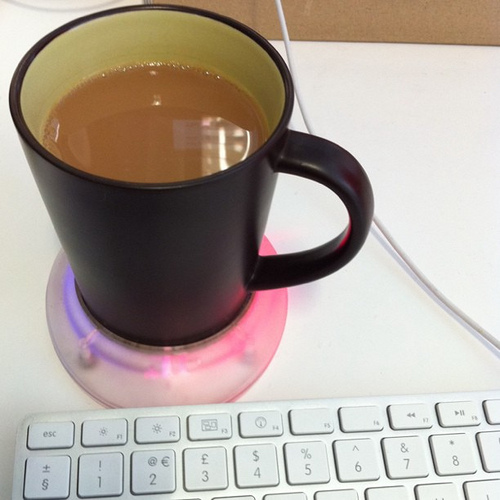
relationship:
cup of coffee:
[4, 3, 379, 352] [21, 55, 287, 197]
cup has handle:
[4, 3, 379, 352] [252, 130, 377, 295]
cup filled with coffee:
[4, 3, 379, 352] [21, 55, 287, 197]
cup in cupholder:
[4, 3, 379, 352] [43, 232, 290, 409]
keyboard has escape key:
[5, 386, 500, 499] [23, 422, 76, 452]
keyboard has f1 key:
[5, 386, 500, 499] [78, 417, 129, 449]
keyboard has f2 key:
[5, 386, 500, 499] [133, 416, 180, 443]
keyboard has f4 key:
[5, 386, 500, 499] [234, 411, 287, 438]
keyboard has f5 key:
[5, 386, 500, 499] [287, 406, 336, 436]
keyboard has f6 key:
[5, 386, 500, 499] [337, 402, 385, 433]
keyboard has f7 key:
[5, 386, 500, 499] [386, 402, 433, 430]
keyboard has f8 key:
[5, 386, 500, 499] [433, 401, 483, 429]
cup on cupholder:
[4, 3, 379, 352] [43, 232, 290, 409]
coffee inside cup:
[21, 55, 287, 197] [4, 3, 379, 352]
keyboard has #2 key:
[5, 386, 500, 499] [126, 447, 179, 496]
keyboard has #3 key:
[5, 386, 500, 499] [178, 444, 231, 491]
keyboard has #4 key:
[5, 386, 500, 499] [229, 443, 282, 490]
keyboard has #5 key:
[5, 386, 500, 499] [281, 438, 333, 487]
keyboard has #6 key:
[5, 386, 500, 499] [329, 436, 382, 485]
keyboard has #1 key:
[5, 386, 500, 499] [73, 449, 120, 500]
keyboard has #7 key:
[5, 386, 500, 499] [380, 433, 429, 480]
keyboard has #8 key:
[5, 386, 500, 499] [425, 431, 477, 477]